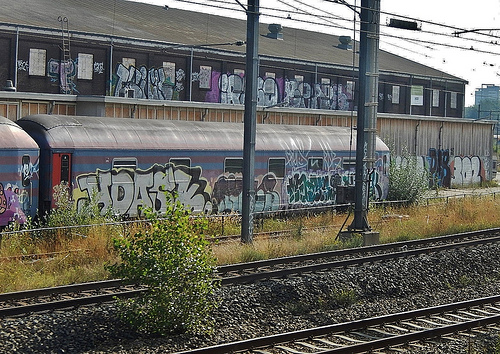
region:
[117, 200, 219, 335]
a small green bush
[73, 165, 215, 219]
graffiti on the train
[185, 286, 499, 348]
a train track on the ground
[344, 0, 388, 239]
a dark light pole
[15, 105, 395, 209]
one train car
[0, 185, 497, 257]
dried yellow grass on the ground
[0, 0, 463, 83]
the roof is dark gray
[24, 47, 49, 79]
a white colored window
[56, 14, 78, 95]
a ladder on the building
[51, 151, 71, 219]
a red train door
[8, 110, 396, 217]
train on a track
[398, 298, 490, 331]
track with no train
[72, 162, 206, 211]
graffiti on the train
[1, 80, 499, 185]
building behind the train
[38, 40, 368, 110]
graffiti on a building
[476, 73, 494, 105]
building in the distance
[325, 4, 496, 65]
lines carrying power supply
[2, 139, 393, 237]
the train has graffiti on it's side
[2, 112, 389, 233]
the train is made of metal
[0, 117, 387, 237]
the train is standing still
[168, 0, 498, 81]
cables are above the train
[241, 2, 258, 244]
a pole is behind the train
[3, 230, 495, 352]
tracks are on the ground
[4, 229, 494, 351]
the tracks are made of metal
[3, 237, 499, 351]
gravel is between the tracks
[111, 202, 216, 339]
a bush is between the tracks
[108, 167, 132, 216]
letter written in graffiti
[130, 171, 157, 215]
letter written in graffiti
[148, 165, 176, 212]
letter written in graffiti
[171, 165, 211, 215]
letter written in graffiti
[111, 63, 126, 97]
letter written in graffiti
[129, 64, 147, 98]
letter written in graffiti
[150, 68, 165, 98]
letter written in graffiti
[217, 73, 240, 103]
letter written in graffiti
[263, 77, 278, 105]
letter written in graffiti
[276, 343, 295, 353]
wooden board between tracks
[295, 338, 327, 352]
wooden board between tracks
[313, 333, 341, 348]
wooden board between tracks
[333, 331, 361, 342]
wooden board between tracks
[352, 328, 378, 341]
wooden board between tracks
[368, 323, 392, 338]
wooden board between tracks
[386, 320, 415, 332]
wooden board between tracks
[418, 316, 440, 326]
wooden board between tracks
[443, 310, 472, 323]
wooden board between tracks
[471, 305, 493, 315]
wooden board between tracks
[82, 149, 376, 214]
graffiti on passenger train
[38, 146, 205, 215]
graffiti on passenger train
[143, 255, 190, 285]
green leaves on brown bush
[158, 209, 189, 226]
green leaves on brown bush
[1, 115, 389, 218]
the train has a lot of graffiti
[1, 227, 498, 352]
the tracks are empty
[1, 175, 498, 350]
the bush between the tracks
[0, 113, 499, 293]
the fence next to the train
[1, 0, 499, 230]
the building next to the train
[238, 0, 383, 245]
the poles are gray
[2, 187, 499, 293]
the grass is tall and overgrown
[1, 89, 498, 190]
the graffiti on the gray wall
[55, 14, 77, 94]
Ladder up the side of building.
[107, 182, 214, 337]
Shrub in between train tracks.